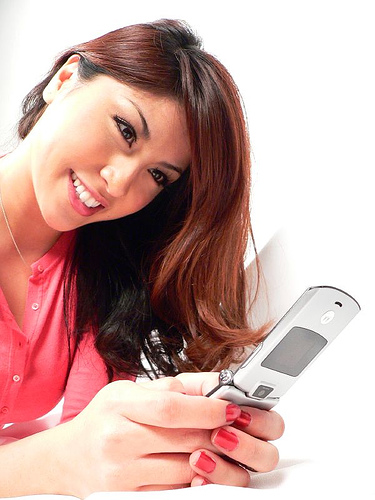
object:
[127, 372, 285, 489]
finger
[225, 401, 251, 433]
fingernail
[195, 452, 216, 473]
polish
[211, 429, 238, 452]
polish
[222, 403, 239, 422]
polish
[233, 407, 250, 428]
polish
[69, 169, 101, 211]
human tooth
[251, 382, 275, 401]
camera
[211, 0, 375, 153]
wall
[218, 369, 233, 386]
phone hinge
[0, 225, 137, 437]
shirt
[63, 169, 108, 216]
smile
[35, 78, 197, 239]
face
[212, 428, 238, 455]
fingernail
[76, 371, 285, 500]
hand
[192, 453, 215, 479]
red fingernail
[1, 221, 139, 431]
blouse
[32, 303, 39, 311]
button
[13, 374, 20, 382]
button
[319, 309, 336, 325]
motorola symbol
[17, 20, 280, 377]
hair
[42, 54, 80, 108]
ear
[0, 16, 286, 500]
girl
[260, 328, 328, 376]
window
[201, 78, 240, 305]
highlights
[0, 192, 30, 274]
necklace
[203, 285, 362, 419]
phone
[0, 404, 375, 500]
blanket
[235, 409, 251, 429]
nailpolish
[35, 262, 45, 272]
button